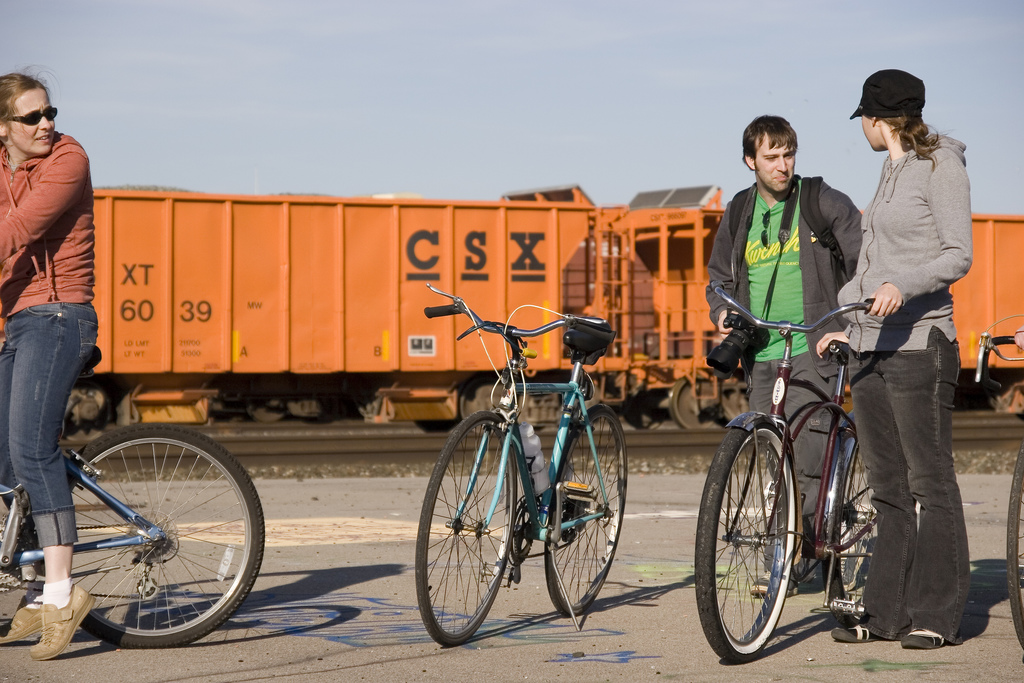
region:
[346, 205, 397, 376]
train has a orange panel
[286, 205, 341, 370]
train has a orange panel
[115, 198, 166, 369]
train has a orange panel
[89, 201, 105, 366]
train has a orange panel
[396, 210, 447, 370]
train has a orange panel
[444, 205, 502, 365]
train has a orange panel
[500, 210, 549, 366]
train has a orange panel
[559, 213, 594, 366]
train has a orange panel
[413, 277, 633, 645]
a bicycle on a stand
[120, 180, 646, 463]
an orange train on the tracks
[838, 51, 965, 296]
a lady wearing a hat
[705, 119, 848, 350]
a man with a green shirt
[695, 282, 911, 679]
a maroon colored bicycle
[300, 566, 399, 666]
concrete pavement with paint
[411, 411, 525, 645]
front wheel of a bicycle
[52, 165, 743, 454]
the train cars are orange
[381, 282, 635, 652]
There is a blue bike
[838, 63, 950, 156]
The woman wears a black hat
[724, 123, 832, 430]
The man wears a green shirt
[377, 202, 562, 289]
The train cars are owned by CSX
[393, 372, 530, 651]
The blue bike has thin tires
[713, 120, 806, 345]
The camera is hung by a camera strap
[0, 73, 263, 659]
woman is on the bike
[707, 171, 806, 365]
man is carrying a camera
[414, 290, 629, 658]
bike color is blue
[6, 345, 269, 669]
bike color is blue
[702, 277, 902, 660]
bike color is brown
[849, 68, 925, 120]
woman is wearing a hat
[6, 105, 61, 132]
woman is wearing sunglasses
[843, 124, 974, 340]
woman is wearing a grey hoodie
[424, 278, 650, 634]
a blue bike with no rider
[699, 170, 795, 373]
a camera around his neck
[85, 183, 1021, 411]
an orange CSX train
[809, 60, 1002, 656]
a woman standing next to a bike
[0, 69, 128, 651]
a woman sitting on a bike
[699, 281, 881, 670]
a brown bike by the woman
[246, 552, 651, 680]
blue writing on the ground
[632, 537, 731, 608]
green writing on the ground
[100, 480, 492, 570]
a yellow square on the ground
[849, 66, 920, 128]
a black cap on her head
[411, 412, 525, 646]
A wheel on a bike.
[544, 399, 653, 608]
A wheel on a bike.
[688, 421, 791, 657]
A wheel on a bike.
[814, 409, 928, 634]
A wheel on a bike.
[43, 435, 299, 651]
A wheel on a bike.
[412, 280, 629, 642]
Blue bicycle standing on pavement.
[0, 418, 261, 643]
Blue bicycle with woman on it.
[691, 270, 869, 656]
Dark red bicycle with woman holding it up.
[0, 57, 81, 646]
Woman in red jacket on a bicycle.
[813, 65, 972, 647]
Woman in grey jacket standing next to a bicycle.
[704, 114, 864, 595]
Man in dark jacket with camera around his neck.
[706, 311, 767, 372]
Black camera with long lens worn on a man.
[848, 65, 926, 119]
Black cap on a woman.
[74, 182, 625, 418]
Orange "CSX" train car on train tracks.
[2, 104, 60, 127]
Black sunglasses worn on a woman.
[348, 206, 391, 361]
train car has a section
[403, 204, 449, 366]
train car has a section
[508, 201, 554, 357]
train car has a section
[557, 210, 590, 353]
train car has a section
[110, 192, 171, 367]
train car has a section